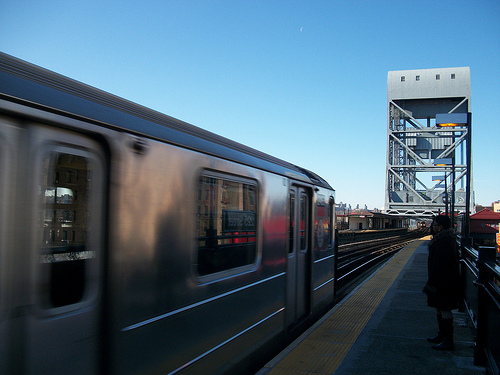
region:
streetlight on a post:
[436, 107, 476, 195]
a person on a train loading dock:
[418, 208, 466, 358]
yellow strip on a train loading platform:
[335, 243, 417, 359]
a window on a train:
[185, 164, 271, 283]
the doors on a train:
[285, 180, 317, 328]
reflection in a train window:
[198, 189, 258, 251]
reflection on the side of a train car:
[125, 161, 192, 286]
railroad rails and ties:
[340, 235, 390, 271]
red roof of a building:
[465, 203, 495, 223]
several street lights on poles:
[427, 98, 471, 208]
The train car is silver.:
[28, 118, 335, 287]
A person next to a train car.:
[421, 208, 476, 345]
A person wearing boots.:
[419, 289, 471, 359]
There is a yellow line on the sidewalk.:
[361, 261, 419, 331]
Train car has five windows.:
[18, 137, 340, 264]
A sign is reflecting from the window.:
[188, 190, 273, 260]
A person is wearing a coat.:
[427, 239, 466, 314]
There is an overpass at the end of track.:
[383, 132, 483, 212]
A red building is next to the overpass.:
[471, 205, 498, 241]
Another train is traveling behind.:
[403, 213, 430, 242]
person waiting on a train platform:
[422, 208, 463, 354]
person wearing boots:
[431, 312, 456, 357]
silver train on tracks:
[3, 50, 340, 373]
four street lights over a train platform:
[423, 106, 475, 243]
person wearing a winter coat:
[423, 228, 467, 309]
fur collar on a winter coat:
[423, 225, 458, 249]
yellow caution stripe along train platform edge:
[233, 225, 435, 373]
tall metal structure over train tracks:
[375, 59, 475, 220]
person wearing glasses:
[428, 220, 444, 226]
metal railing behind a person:
[456, 232, 499, 374]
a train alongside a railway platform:
[0, 43, 498, 374]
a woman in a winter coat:
[421, 207, 468, 359]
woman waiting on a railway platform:
[418, 210, 472, 353]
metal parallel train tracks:
[337, 229, 435, 294]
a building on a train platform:
[345, 205, 413, 232]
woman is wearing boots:
[421, 210, 465, 355]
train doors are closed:
[281, 175, 317, 333]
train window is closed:
[36, 145, 93, 314]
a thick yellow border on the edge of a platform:
[255, 231, 430, 373]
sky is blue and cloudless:
[3, 2, 499, 212]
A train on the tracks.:
[2, 49, 344, 373]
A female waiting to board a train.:
[411, 210, 471, 366]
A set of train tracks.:
[329, 235, 427, 282]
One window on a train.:
[179, 158, 266, 289]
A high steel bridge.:
[380, 64, 479, 249]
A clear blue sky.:
[0, 4, 496, 218]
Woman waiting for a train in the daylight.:
[418, 203, 469, 363]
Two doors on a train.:
[276, 173, 316, 336]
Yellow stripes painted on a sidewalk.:
[261, 238, 428, 373]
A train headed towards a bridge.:
[5, 39, 497, 367]